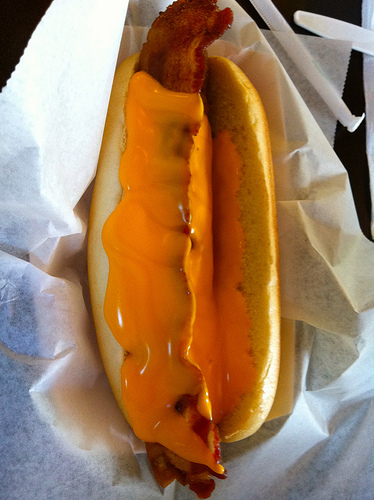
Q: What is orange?
A: Cheese.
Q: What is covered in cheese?
A: Bacon.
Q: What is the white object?
A: Paper.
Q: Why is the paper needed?
A: To prevent mess.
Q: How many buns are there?
A: 1.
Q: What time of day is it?
A: Day time.